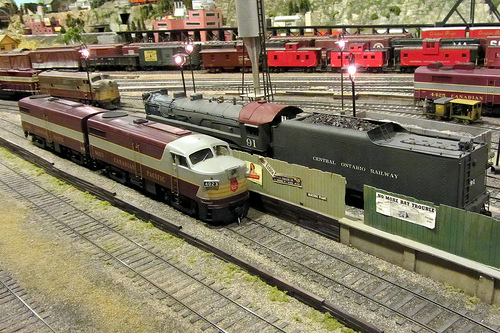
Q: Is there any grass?
A: Yes, there is grass.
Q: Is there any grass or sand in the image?
A: Yes, there is grass.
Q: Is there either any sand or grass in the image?
A: Yes, there is grass.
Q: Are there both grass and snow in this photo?
A: No, there is grass but no snow.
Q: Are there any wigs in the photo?
A: No, there are no wigs.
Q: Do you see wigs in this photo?
A: No, there are no wigs.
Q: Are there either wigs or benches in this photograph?
A: No, there are no wigs or benches.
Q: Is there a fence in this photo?
A: Yes, there is a fence.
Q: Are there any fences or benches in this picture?
A: Yes, there is a fence.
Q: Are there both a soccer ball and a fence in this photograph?
A: No, there is a fence but no soccer balls.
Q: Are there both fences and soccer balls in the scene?
A: No, there is a fence but no soccer balls.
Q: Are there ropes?
A: No, there are no ropes.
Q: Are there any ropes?
A: No, there are no ropes.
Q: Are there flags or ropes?
A: No, there are no ropes or flags.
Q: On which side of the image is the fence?
A: The fence is on the right of the image.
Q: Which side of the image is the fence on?
A: The fence is on the right of the image.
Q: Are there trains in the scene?
A: Yes, there is a train.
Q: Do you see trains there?
A: Yes, there is a train.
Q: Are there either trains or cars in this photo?
A: Yes, there is a train.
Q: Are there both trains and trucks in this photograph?
A: No, there is a train but no trucks.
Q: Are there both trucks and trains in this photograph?
A: No, there is a train but no trucks.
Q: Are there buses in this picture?
A: No, there are no buses.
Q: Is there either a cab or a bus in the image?
A: No, there are no buses or taxis.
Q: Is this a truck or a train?
A: This is a train.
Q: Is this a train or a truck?
A: This is a train.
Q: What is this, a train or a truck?
A: This is a train.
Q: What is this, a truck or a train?
A: This is a train.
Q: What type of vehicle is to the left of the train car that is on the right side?
A: The vehicle is a train.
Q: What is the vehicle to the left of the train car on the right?
A: The vehicle is a train.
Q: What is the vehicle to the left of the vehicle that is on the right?
A: The vehicle is a train.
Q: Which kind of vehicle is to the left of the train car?
A: The vehicle is a train.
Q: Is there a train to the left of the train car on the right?
A: Yes, there is a train to the left of the train car.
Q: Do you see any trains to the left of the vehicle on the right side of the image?
A: Yes, there is a train to the left of the train car.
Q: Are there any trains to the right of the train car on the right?
A: No, the train is to the left of the train car.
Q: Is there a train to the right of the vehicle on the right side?
A: No, the train is to the left of the train car.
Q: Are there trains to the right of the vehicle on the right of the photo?
A: No, the train is to the left of the train car.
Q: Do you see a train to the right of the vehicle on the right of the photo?
A: No, the train is to the left of the train car.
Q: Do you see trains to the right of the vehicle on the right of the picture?
A: No, the train is to the left of the train car.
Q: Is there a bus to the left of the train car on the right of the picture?
A: No, there is a train to the left of the train car.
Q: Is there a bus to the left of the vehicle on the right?
A: No, there is a train to the left of the train car.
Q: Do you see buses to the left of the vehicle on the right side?
A: No, there is a train to the left of the train car.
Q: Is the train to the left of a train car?
A: Yes, the train is to the left of a train car.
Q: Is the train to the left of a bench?
A: No, the train is to the left of a train car.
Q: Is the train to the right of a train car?
A: No, the train is to the left of a train car.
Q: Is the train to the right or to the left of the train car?
A: The train is to the left of the train car.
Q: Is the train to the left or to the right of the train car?
A: The train is to the left of the train car.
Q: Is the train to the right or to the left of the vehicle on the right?
A: The train is to the left of the train car.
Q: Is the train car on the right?
A: Yes, the train car is on the right of the image.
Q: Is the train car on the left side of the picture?
A: No, the train car is on the right of the image.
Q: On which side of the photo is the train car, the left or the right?
A: The train car is on the right of the image.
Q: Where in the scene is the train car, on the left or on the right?
A: The train car is on the right of the image.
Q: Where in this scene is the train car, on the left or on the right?
A: The train car is on the right of the image.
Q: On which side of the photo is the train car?
A: The train car is on the right of the image.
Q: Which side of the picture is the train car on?
A: The train car is on the right of the image.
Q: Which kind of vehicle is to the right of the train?
A: The vehicle is a train car.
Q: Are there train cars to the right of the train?
A: Yes, there is a train car to the right of the train.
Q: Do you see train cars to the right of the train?
A: Yes, there is a train car to the right of the train.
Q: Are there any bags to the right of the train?
A: No, there is a train car to the right of the train.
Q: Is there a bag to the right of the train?
A: No, there is a train car to the right of the train.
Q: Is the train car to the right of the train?
A: Yes, the train car is to the right of the train.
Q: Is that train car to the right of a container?
A: No, the train car is to the right of the train.